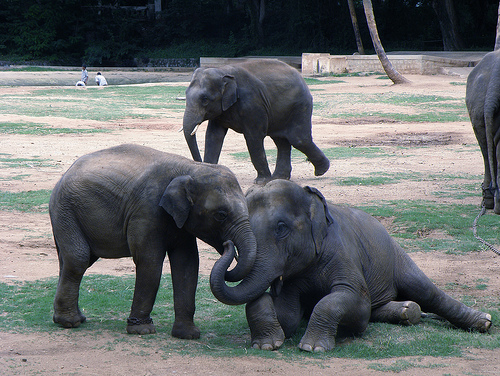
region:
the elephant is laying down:
[223, 181, 490, 348]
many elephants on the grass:
[0, 49, 499, 373]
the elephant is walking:
[184, 58, 324, 188]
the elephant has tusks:
[178, 123, 200, 135]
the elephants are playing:
[54, 140, 491, 351]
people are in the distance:
[73, 67, 109, 86]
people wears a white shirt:
[96, 75, 106, 85]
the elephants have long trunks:
[45, 52, 497, 347]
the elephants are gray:
[51, 50, 498, 350]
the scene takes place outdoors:
[1, 0, 499, 374]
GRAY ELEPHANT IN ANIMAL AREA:
[179, 50, 350, 173]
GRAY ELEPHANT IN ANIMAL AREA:
[41, 135, 257, 345]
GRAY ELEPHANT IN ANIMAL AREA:
[205, 177, 495, 354]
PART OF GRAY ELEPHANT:
[461, 40, 497, 212]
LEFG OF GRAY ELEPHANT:
[295, 290, 366, 356]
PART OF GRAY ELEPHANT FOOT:
[381, 295, 422, 330]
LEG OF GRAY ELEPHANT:
[410, 272, 495, 332]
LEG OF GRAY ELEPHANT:
[238, 295, 293, 355]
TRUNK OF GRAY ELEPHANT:
[205, 236, 283, 304]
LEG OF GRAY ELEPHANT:
[119, 250, 162, 342]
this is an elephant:
[37, 125, 262, 356]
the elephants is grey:
[198, 141, 499, 369]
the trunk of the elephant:
[202, 227, 286, 304]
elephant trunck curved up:
[192, 235, 279, 300]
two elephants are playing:
[15, 115, 487, 371]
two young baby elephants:
[31, 107, 498, 359]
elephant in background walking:
[148, 47, 360, 190]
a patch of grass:
[28, 71, 158, 127]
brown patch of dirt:
[351, 118, 458, 210]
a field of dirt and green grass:
[0, 66, 499, 374]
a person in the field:
[95, 71, 107, 84]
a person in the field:
[80, 64, 87, 84]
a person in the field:
[76, 80, 84, 86]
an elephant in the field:
[177, 58, 329, 185]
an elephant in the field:
[48, 143, 255, 339]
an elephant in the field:
[209, 178, 491, 353]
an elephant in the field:
[465, 48, 499, 215]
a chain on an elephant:
[472, 182, 498, 254]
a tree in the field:
[361, 0, 413, 84]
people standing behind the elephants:
[76, 66, 108, 85]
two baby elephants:
[47, 144, 491, 347]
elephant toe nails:
[296, 338, 323, 353]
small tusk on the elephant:
[188, 123, 199, 137]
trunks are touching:
[210, 222, 270, 306]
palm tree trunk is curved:
[361, 0, 406, 82]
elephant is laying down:
[221, 178, 491, 350]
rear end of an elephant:
[464, 47, 498, 209]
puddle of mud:
[377, 128, 454, 145]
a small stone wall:
[302, 55, 470, 72]